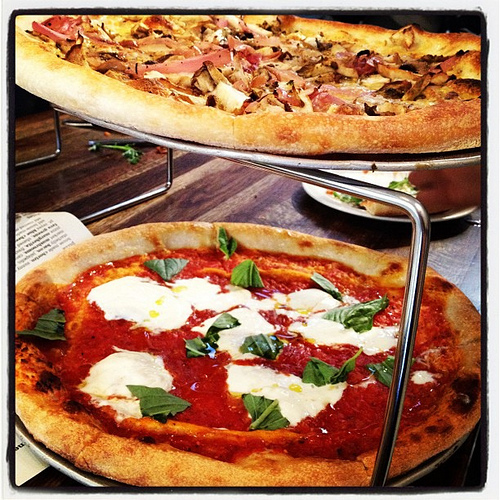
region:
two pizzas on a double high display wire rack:
[15, 7, 477, 484]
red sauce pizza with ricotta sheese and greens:
[16, 219, 481, 481]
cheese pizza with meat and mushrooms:
[14, 11, 478, 158]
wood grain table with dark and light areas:
[19, 135, 284, 219]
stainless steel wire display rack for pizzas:
[59, 147, 429, 484]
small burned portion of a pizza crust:
[446, 370, 477, 418]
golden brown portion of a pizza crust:
[23, 417, 360, 484]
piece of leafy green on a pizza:
[128, 384, 190, 421]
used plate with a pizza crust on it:
[299, 168, 473, 223]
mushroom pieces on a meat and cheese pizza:
[366, 41, 473, 101]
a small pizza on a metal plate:
[13, 220, 480, 496]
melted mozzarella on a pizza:
[78, 347, 173, 422]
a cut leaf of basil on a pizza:
[125, 384, 189, 419]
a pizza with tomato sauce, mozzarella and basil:
[12, 219, 483, 491]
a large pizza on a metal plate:
[14, 15, 484, 164]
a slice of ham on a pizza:
[141, 50, 230, 75]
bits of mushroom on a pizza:
[188, 60, 228, 96]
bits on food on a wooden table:
[91, 130, 166, 162]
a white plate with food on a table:
[302, 170, 480, 221]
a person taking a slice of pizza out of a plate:
[409, 163, 484, 218]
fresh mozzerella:
[88, 277, 190, 330]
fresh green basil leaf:
[232, 263, 264, 286]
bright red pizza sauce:
[173, 358, 219, 389]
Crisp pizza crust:
[54, 254, 79, 276]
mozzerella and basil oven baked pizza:
[11, 220, 483, 490]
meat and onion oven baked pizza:
[13, 14, 486, 158]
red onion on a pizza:
[125, 50, 227, 73]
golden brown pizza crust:
[220, 111, 481, 149]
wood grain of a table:
[173, 168, 258, 220]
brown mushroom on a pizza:
[190, 62, 231, 89]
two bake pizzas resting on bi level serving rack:
[23, 14, 498, 482]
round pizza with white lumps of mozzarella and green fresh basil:
[25, 224, 472, 474]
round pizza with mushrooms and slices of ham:
[11, 13, 488, 156]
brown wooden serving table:
[18, 120, 473, 482]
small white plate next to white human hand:
[315, 166, 480, 230]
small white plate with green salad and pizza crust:
[306, 168, 488, 225]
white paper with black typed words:
[15, 205, 92, 280]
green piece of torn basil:
[124, 377, 189, 429]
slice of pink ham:
[148, 44, 236, 73]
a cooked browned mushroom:
[359, 98, 404, 114]